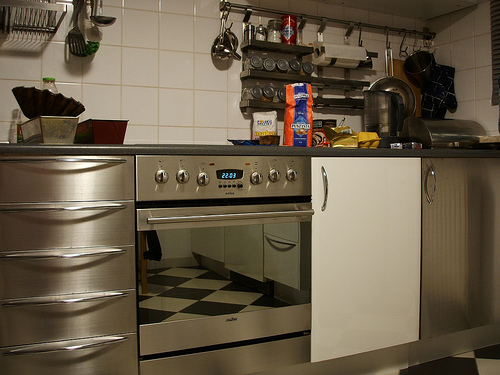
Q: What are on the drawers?
A: Handles.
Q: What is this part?
A: Countertop.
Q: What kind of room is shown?
A: Kitchen.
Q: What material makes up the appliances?
A: Stainless steel.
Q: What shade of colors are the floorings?
A: Black and white.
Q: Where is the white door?
A: Next to the oven.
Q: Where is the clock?
A: On the oven.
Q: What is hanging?
A: Utensils.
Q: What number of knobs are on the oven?
A: 6.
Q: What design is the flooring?
A: Checkered tile.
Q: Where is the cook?
A: Noone is in the photo.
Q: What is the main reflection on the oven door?
A: Floor.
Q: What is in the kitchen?
A: An oven.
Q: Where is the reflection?
A: On the oven door.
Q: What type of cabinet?
A: White cabinet.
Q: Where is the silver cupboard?
A: By the white one.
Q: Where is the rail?
A: On the wall.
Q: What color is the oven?
A: Silver.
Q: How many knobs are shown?
A: Six.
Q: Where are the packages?
A: The counter.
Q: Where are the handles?
A: On cabinets.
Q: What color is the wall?
A: White.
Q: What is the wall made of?
A: Tile.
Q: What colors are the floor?
A: Black and White.